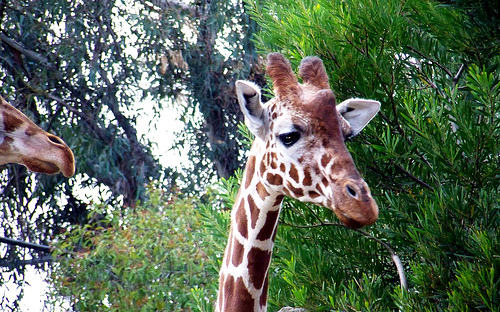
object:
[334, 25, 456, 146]
tree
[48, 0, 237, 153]
trees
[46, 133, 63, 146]
nostril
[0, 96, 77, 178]
giraffe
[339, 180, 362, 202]
nostril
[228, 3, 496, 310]
tree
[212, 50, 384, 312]
giraffe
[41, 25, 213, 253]
tree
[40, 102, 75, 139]
leaves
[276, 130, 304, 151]
giraffe's eye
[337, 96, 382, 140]
ear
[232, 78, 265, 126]
ear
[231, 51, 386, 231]
head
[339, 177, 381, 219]
nose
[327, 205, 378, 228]
mouth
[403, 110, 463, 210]
tree